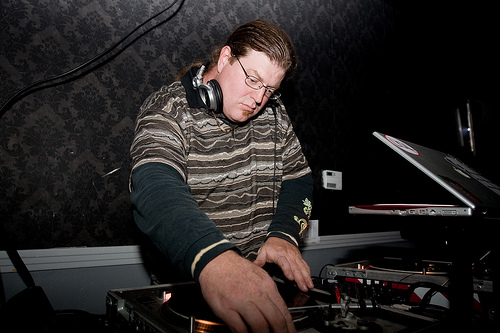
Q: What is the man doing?
A: Playing a record.